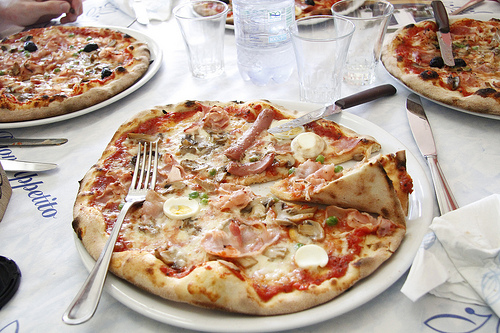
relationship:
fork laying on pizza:
[64, 139, 158, 324] [74, 101, 414, 313]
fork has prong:
[64, 139, 158, 324] [148, 141, 161, 190]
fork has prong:
[64, 139, 158, 324] [143, 139, 152, 189]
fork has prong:
[64, 139, 158, 324] [135, 141, 149, 189]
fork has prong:
[64, 139, 158, 324] [129, 139, 142, 188]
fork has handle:
[64, 139, 158, 324] [62, 198, 133, 326]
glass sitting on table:
[168, 0, 229, 81] [0, 2, 499, 331]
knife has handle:
[266, 81, 398, 138] [335, 82, 395, 113]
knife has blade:
[266, 81, 398, 138] [270, 102, 342, 134]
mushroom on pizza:
[162, 193, 200, 220] [74, 101, 414, 313]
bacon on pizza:
[207, 213, 277, 256] [74, 101, 414, 313]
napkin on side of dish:
[399, 185, 499, 319] [73, 99, 435, 332]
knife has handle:
[267, 84, 396, 134] [335, 82, 395, 113]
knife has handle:
[405, 91, 441, 158] [425, 153, 457, 217]